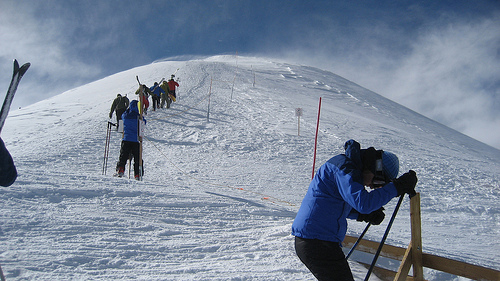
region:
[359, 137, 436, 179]
person has blue cap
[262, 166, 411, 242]
person has blue coat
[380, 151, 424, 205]
person has black gloves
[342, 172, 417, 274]
person holds two ski poles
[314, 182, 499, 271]
person leans against wooden fence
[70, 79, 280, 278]
many ski tracks on large hill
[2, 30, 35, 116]
person on left is holding skis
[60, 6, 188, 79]
sky is blue and cloudy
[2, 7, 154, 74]
wispy white clouds in sky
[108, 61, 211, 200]
people skiing on tall hill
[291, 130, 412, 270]
Person wearing a blue jacket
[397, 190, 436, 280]
The post is wood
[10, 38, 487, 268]
The hill is covered in snow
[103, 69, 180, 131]
People walking up the mountain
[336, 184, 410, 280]
The ski poles are black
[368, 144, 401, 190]
The goggles are black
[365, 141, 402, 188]
The hat is blue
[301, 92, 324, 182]
The stick is red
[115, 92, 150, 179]
Person wearing black pants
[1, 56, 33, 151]
The skis are black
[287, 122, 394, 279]
man is wearing blue coat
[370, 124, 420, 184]
man is wearing blue cap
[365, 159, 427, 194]
man is wearing black gloves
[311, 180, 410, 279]
man is holding dark skis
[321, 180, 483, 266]
man is standing against wooden fence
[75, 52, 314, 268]
tall hill covered with white snow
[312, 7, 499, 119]
sky is blue with wispy white clouds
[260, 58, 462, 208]
tracks made on side of hill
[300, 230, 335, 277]
man is wearing black pants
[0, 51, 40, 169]
person holding skis to left of man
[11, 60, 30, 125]
person is holding skis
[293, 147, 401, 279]
skier is next to the wooden fence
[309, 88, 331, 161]
red pole in the snow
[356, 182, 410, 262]
woman using her ski poles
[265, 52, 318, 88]
prints in the snow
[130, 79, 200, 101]
skiers walking up the slope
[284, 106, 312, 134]
sign in the snow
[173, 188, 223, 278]
snow is covering the slope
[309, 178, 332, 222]
person is wearing a blue jacket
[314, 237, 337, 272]
person has on black ski pants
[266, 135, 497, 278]
Skier leaning on a wooden fence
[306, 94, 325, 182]
Thin, red stalk stuck in the snow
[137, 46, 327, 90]
Dome top of a snow mount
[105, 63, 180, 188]
Line of skiers walking up the snow mount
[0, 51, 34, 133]
Pair of skis held above the ground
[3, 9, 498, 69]
Light cloud covered sky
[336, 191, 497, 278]
Wooden fencing going into the snow ground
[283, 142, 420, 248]
Skier's thick blue jacket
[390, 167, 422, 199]
Dark black gloves holding the wood top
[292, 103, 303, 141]
Sign stuck onthe snow covered surface